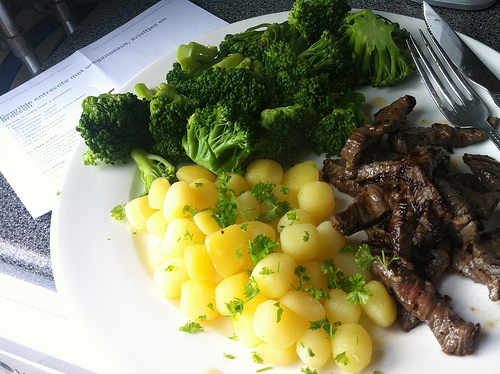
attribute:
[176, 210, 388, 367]
potatoes — yellow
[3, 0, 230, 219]
recipe — printed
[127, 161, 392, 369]
potatoes — peeled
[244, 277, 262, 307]
parsley — green 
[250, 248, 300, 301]
potato — tiny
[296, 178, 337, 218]
potato — tiny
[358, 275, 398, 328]
potato — tiny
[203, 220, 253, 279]
potato — tiny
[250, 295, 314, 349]
potato — tiny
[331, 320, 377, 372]
potato — little, round, boiled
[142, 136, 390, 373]
potatoes — yellow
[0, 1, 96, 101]
floor — blue, white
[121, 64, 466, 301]
food — round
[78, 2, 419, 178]
broccoli — green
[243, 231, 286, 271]
herb — green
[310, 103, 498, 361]
steak — cut, grilled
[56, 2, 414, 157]
broccoli — green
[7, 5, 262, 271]
countertop — gray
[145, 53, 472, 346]
food — home-cooked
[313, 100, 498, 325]
steak — grilled, cut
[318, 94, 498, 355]
meat — grilled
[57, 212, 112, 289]
plate — white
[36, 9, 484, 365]
plate — white 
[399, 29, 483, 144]
fork — silver